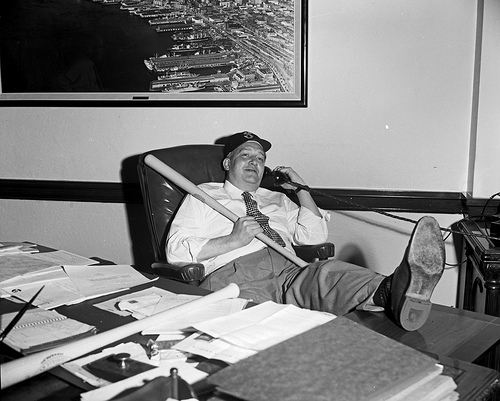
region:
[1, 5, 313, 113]
a photo on a wall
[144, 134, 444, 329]
a man sitting in a chair with his foot resting on a desk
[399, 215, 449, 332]
the bottom of a show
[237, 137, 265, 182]
the face of a man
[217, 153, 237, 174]
the ear of a man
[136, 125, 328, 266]
a man holding a bat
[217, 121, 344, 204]
a man with a phone in his hand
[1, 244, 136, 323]
the papers on a desk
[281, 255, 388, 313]
the leg of a man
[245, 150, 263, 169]
the nose of a man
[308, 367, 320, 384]
part of a cober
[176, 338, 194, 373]
part of a paper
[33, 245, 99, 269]
white paper on desk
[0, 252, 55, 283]
white paper on desk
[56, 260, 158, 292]
white paper on desk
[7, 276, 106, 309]
white paper on desk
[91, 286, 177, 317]
white paper on desk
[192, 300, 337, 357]
white paper on desk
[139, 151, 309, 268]
baseball bat made of wood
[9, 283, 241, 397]
baseball bat made of wood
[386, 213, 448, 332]
black colored dress shoe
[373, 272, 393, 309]
black colored dress sock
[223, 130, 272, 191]
The man is wearing a cap.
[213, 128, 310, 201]
The man is holding a phone.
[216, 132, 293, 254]
The man is wearing a tie.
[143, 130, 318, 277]
The man is holding a baseball bat.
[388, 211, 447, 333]
The man is wearing a shoe.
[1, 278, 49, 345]
The pen on the desk is black.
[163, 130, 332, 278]
The man is wearing a white shirt.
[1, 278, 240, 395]
There is a bat on the man's desk.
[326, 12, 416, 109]
The wall in the background is light in color.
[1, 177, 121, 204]
The wall trim is dark in color.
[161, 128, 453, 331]
man sitting at a desk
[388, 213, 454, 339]
shoe on the desk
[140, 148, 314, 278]
bat in the man's hand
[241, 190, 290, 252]
man's polka dotted tie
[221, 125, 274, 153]
baseball cap on a man's head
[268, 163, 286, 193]
phone in a man's hand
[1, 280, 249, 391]
wooden bat on the desk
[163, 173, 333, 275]
man's white shirt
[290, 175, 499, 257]
phone wire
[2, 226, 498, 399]
desk cluttered with papers